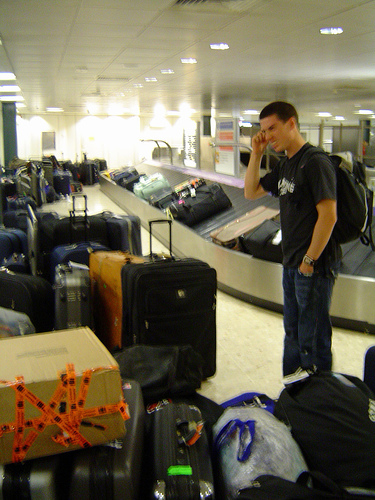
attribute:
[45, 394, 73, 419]
tape — orange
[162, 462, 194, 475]
tag — green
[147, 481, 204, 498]
tips — metal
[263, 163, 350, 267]
shirt — black, short sleeve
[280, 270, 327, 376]
jeans — blue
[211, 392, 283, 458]
handles — blue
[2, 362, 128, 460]
tape — orange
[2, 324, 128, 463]
box — cardboard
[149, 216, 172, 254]
handle — extended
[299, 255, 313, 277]
hand — left hand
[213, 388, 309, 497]
bag — duffel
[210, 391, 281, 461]
strap — blue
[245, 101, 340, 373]
man — young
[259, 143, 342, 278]
shirt — black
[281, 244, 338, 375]
jeans — blue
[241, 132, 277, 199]
arm — up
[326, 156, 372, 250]
backpack — black